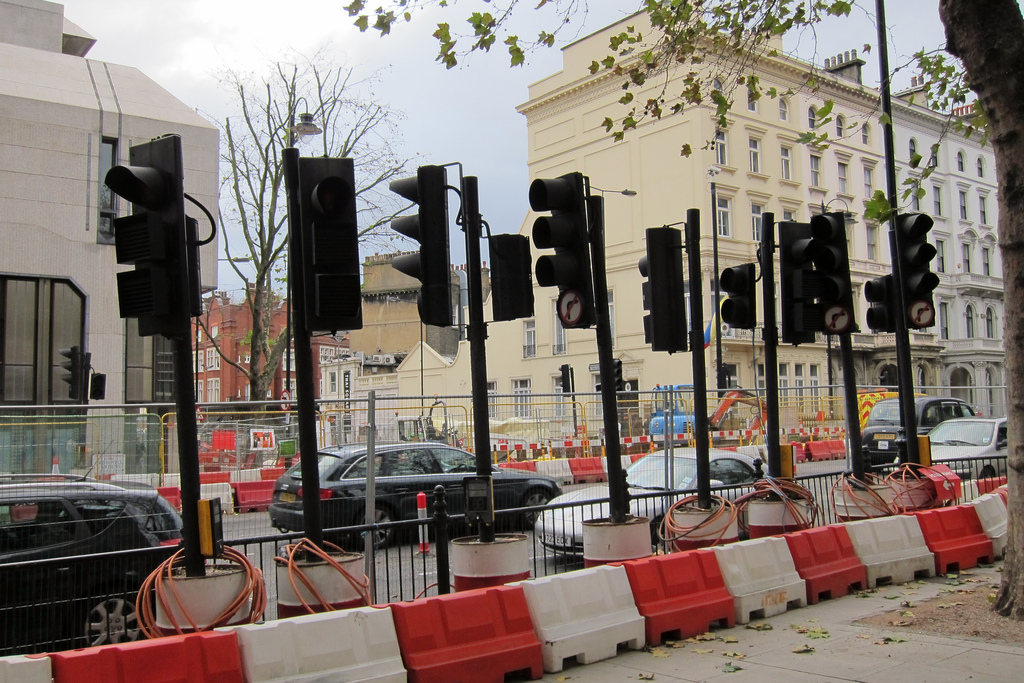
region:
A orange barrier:
[394, 581, 541, 668]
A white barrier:
[514, 560, 642, 658]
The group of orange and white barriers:
[69, 487, 1014, 628]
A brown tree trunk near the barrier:
[927, 14, 1022, 615]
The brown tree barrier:
[922, 1, 1020, 611]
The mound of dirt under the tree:
[862, 560, 1019, 644]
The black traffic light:
[75, 117, 231, 349]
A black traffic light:
[262, 140, 384, 336]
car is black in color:
[265, 423, 576, 545]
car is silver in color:
[527, 434, 762, 551]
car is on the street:
[276, 434, 542, 533]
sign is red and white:
[555, 289, 597, 337]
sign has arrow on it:
[548, 288, 584, 324]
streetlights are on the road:
[87, 140, 189, 330]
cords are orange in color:
[282, 531, 381, 614]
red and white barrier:
[388, 534, 1012, 653]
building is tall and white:
[529, 30, 1021, 433]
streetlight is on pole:
[260, 63, 334, 139]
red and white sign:
[537, 283, 596, 335]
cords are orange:
[135, 533, 271, 638]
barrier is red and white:
[265, 492, 983, 614]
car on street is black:
[243, 428, 563, 524]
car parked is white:
[512, 432, 787, 540]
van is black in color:
[857, 379, 991, 466]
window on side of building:
[12, 226, 112, 496]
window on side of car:
[366, 441, 442, 479]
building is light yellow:
[503, 42, 1013, 432]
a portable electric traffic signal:
[99, 134, 204, 337]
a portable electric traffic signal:
[289, 156, 363, 333]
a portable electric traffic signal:
[387, 162, 451, 325]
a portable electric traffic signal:
[528, 168, 585, 290]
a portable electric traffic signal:
[634, 223, 685, 351]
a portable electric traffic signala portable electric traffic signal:
[776, 216, 821, 346]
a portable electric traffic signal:
[807, 210, 852, 299]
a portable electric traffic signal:
[893, 209, 939, 301]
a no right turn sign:
[904, 295, 937, 330]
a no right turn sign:
[554, 289, 586, 327]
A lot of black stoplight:
[34, 192, 943, 379]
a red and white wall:
[367, 532, 839, 681]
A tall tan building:
[563, 46, 791, 518]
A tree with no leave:
[186, 46, 370, 568]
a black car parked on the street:
[240, 388, 572, 629]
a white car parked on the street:
[498, 442, 774, 655]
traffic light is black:
[101, 134, 210, 576]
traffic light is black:
[281, 146, 366, 561]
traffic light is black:
[390, 161, 538, 539]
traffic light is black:
[528, 167, 633, 521]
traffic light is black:
[640, 210, 714, 510]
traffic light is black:
[716, 212, 827, 483]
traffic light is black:
[813, 214, 873, 496]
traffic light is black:
[862, 212, 940, 477]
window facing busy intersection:
[747, 136, 758, 173]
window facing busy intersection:
[776, 144, 791, 181]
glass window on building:
[712, 110, 728, 171]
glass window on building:
[714, 185, 731, 236]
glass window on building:
[746, 87, 760, 110]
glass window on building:
[744, 129, 763, 178]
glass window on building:
[779, 90, 790, 120]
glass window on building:
[809, 151, 823, 189]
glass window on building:
[775, 366, 791, 404]